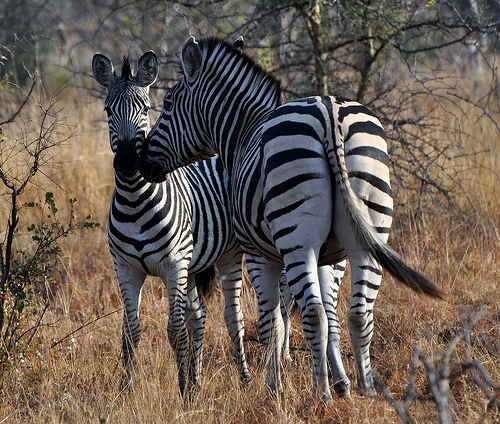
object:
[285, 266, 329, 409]
leg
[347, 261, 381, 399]
leg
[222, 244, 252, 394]
leg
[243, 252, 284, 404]
leg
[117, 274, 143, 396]
leg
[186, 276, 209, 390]
leg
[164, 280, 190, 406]
leg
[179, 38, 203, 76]
ear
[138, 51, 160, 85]
ear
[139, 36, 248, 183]
head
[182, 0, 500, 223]
trees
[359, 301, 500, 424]
twigs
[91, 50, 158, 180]
head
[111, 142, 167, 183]
nose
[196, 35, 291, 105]
mane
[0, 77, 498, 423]
grass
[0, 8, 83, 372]
plants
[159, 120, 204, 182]
jaw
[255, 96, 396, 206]
hip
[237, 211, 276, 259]
stomach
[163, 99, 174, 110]
eye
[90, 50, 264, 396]
zebra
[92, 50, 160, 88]
ears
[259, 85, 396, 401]
rear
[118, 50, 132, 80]
mane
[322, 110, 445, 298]
tail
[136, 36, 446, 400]
zebra